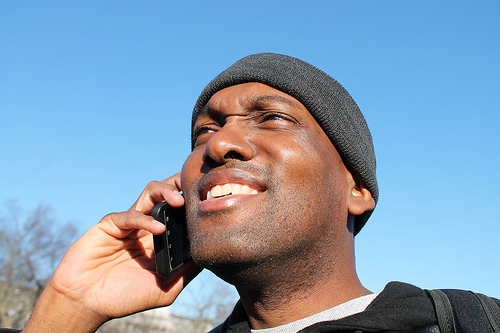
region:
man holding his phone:
[106, 42, 378, 330]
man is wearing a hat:
[172, 47, 404, 219]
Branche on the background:
[1, 191, 55, 271]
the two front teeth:
[207, 182, 242, 201]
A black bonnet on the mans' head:
[189, 39, 368, 131]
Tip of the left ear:
[348, 197, 376, 226]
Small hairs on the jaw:
[188, 221, 287, 277]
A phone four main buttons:
[162, 210, 186, 269]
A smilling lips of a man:
[186, 165, 289, 242]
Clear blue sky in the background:
[26, 33, 158, 153]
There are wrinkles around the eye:
[241, 102, 313, 137]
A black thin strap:
[423, 280, 462, 332]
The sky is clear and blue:
[371, 24, 475, 207]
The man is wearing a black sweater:
[341, 284, 496, 331]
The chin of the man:
[178, 218, 268, 273]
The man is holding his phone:
[44, 158, 225, 328]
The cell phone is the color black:
[144, 195, 194, 279]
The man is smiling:
[180, 158, 277, 221]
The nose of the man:
[196, 115, 256, 170]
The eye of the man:
[246, 100, 302, 141]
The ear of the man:
[338, 156, 377, 218]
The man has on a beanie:
[151, 53, 398, 250]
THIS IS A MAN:
[16, 49, 498, 331]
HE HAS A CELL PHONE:
[148, 190, 187, 288]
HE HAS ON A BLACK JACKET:
[190, 280, 495, 331]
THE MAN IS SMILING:
[4, 43, 496, 331]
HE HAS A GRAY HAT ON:
[188, 49, 383, 236]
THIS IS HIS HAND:
[45, 170, 205, 318]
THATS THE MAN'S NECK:
[231, 252, 362, 332]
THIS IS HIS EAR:
[345, 170, 376, 217]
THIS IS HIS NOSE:
[197, 133, 253, 165]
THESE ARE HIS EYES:
[180, 110, 297, 141]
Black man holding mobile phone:
[27, 51, 498, 331]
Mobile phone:
[151, 193, 193, 282]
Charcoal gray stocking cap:
[189, 49, 379, 237]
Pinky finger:
[103, 209, 166, 242]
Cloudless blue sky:
[0, 1, 498, 52]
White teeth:
[200, 180, 261, 199]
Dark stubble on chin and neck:
[183, 163, 339, 306]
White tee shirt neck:
[249, 293, 387, 332]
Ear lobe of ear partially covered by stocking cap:
[347, 190, 374, 212]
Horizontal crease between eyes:
[219, 111, 251, 120]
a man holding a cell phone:
[127, 114, 212, 294]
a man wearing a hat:
[197, 40, 378, 166]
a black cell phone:
[151, 196, 205, 283]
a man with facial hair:
[195, 200, 312, 313]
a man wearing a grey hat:
[184, 41, 371, 170]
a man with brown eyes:
[189, 105, 313, 137]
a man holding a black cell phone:
[137, 162, 203, 294]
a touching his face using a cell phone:
[108, 152, 190, 312]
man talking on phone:
[16, 52, 498, 331]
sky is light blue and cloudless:
[2, 1, 498, 312]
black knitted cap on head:
[191, 51, 381, 237]